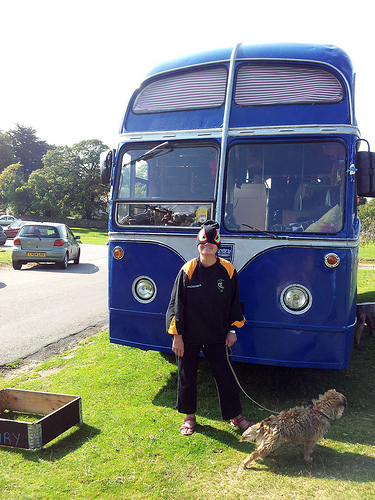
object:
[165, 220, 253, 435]
person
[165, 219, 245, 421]
costume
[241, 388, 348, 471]
dog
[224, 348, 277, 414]
leash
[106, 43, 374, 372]
bus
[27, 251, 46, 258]
plate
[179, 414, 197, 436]
sandal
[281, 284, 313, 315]
light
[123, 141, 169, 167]
wiper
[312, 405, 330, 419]
collar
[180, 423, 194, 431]
straps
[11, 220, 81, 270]
car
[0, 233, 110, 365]
street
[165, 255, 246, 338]
jacket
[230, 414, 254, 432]
sandles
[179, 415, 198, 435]
feet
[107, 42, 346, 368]
front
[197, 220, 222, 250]
hat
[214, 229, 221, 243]
eyes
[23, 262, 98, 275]
shadow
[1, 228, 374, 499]
grass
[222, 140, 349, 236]
windshields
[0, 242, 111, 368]
pavement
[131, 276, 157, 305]
lights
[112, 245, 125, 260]
lights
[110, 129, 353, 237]
sleeper cab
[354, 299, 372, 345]
man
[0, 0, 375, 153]
sky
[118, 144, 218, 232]
window